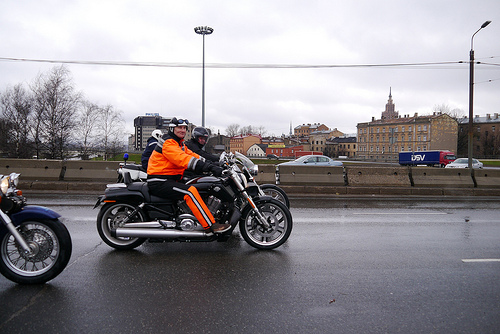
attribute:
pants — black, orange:
[142, 177, 214, 227]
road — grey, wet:
[303, 182, 469, 317]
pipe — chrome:
[116, 225, 217, 237]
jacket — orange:
[141, 132, 206, 196]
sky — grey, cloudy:
[4, 0, 498, 152]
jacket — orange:
[143, 134, 205, 176]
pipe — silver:
[110, 217, 217, 250]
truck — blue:
[383, 140, 490, 189]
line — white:
[458, 255, 498, 265]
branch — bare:
[58, 75, 73, 85]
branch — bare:
[37, 69, 44, 83]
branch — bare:
[57, 62, 64, 72]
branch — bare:
[59, 70, 69, 78]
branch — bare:
[52, 97, 71, 104]